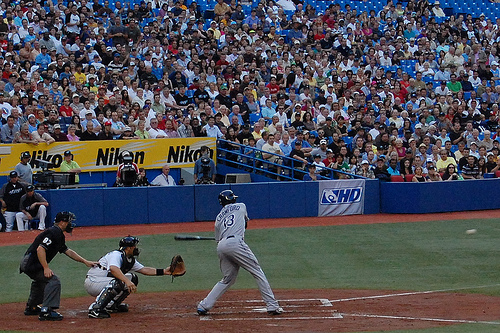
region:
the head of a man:
[203, 185, 248, 228]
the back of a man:
[214, 179, 251, 246]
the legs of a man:
[180, 233, 310, 321]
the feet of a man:
[186, 283, 319, 320]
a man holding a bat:
[186, 155, 299, 269]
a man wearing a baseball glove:
[93, 219, 217, 296]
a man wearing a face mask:
[40, 202, 98, 242]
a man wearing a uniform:
[201, 176, 259, 317]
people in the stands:
[225, 88, 377, 191]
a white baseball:
[465, 227, 477, 239]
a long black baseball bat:
[171, 232, 216, 244]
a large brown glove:
[165, 252, 188, 279]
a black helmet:
[216, 187, 241, 202]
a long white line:
[345, 306, 498, 328]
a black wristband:
[150, 264, 165, 276]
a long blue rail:
[217, 136, 357, 187]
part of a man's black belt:
[92, 259, 109, 271]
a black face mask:
[67, 214, 78, 235]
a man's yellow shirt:
[434, 156, 458, 168]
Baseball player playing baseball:
[171, 187, 285, 317]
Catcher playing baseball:
[81, 234, 189, 320]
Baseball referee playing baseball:
[16, 208, 101, 323]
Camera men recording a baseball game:
[13, 144, 218, 190]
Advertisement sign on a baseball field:
[317, 178, 365, 217]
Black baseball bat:
[171, 232, 216, 243]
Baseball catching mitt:
[167, 254, 185, 276]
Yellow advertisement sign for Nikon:
[0, 137, 216, 176]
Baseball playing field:
[1, 209, 497, 331]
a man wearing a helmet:
[215, 181, 242, 210]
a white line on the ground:
[312, 289, 337, 312]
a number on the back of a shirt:
[217, 203, 242, 238]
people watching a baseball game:
[58, 65, 107, 120]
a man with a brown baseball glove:
[140, 248, 194, 284]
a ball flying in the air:
[453, 220, 479, 240]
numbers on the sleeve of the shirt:
[38, 227, 54, 252]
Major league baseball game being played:
[6, 8, 478, 306]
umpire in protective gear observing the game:
[17, 205, 85, 322]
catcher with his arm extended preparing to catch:
[79, 230, 188, 321]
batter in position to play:
[171, 169, 295, 329]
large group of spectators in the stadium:
[6, 8, 498, 163]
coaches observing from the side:
[1, 169, 48, 231]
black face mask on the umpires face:
[56, 210, 79, 237]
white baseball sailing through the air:
[464, 225, 479, 239]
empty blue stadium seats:
[457, 2, 498, 16]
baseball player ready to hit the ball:
[173, 188, 283, 317]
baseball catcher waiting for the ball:
[83, 234, 187, 320]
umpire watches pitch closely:
[16, 208, 100, 322]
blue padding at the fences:
[41, 176, 498, 227]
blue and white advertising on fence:
[317, 179, 365, 216]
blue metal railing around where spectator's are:
[217, 138, 363, 179]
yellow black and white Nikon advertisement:
[0, 137, 217, 177]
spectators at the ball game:
[0, 1, 497, 179]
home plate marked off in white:
[203, 297, 339, 321]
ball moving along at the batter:
[463, 225, 481, 235]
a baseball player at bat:
[172, 190, 283, 313]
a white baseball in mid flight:
[465, 227, 475, 233]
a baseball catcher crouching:
[83, 232, 185, 318]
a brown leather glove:
[171, 252, 186, 277]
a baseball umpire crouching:
[17, 212, 96, 319]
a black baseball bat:
[172, 234, 210, 240]